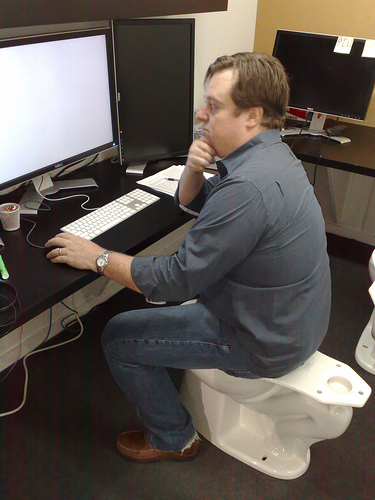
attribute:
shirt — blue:
[151, 139, 316, 380]